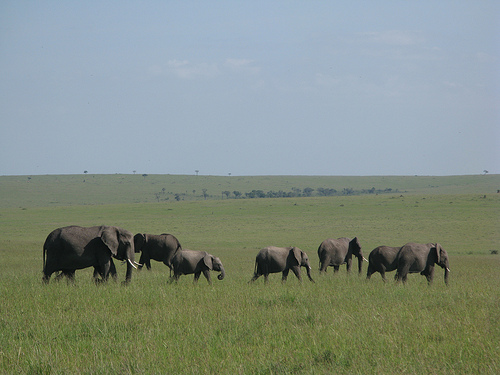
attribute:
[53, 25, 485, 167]
clouds — thin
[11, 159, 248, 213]
hill — grassy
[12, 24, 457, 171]
sky — clear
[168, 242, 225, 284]
elephants — baby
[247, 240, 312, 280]
elephants — baby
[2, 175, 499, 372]
grass — tall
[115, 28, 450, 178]
sky — Clear 